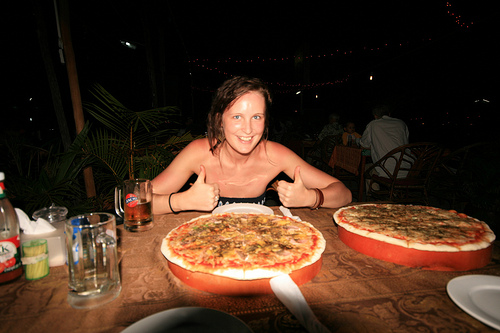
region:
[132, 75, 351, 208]
A woman that is smiling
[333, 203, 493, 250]
Fresh pizza on a table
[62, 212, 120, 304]
An empty glass mug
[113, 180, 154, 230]
A glass mug with a drink in it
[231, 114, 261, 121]
Blue eyes on a woman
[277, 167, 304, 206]
A thumbs up signal from a lady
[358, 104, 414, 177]
A man eating at a table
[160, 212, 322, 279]
A delicious pizza with toppings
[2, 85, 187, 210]
Tropical plants outside a restaurant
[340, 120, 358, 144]
A child sitting at a table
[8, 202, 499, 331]
items laid out on a large table with wooden appearance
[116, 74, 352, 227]
woman with her arms on table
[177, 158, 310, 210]
woman giving thumb-up gesture with both hands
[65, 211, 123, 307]
an empty beer glass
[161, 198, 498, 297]
two large pizzas on trays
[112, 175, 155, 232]
amber liquid in beer glass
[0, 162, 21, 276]
container with red, white and green label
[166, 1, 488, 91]
white string lights in background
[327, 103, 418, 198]
child and adult sitting at a table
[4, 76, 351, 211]
green plant behind woman on the left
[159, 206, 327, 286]
A pizza on the table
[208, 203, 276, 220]
A whiute plate on the table top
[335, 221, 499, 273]
The red pizza trey with the pizza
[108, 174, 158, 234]
A mug full of liquid on the table.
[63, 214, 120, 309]
an empty clear glass mug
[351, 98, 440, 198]
A person in the chair behind the table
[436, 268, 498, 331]
A white round plte on the top of the table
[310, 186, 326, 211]
The brown wrist bands on the girl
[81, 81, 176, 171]
The plant next to the womens arm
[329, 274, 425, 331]
The brown fabrics with designs on the table top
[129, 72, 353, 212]
a woman seated at table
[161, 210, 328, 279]
a large pizza pie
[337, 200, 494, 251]
a large pizza pie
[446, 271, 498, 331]
a white dinner plate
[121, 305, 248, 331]
a white dinner plate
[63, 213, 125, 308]
a clear glass mug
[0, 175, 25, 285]
a clear bottle of sauce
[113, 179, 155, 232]
a clear glass mug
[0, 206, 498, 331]
a brown patterned tablecloth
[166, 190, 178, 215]
a thin black bracelet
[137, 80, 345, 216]
the woman is holding her thumbs up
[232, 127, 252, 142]
the woman is smiling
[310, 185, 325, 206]
the woman is wearing bracelets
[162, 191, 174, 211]
the woman is wearing a bracelet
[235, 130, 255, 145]
the woman is grinning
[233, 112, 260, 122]
the woman has blue eyes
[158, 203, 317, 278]
the pizza is in front of the woman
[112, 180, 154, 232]
the mug is on the table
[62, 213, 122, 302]
a mug is empty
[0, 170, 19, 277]
a bottle is on the table